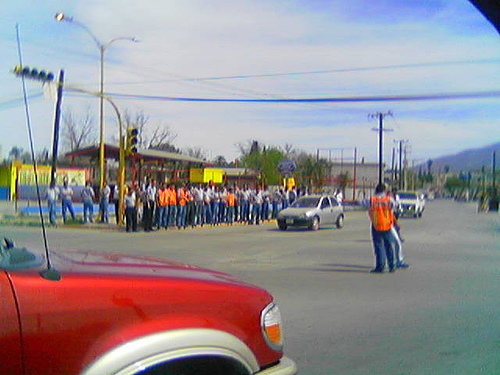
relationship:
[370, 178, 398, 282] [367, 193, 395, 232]
man wearing orange vest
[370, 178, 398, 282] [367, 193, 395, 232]
man wearing a vest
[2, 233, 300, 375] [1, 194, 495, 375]
suv driving on street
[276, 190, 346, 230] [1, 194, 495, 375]
car rolling on street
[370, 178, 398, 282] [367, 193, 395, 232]
man wearing vest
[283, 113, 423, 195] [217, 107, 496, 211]
powerlines are in distance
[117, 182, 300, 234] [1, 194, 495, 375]
people standing on street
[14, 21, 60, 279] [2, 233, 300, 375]
attenna in suv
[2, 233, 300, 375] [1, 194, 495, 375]
suv parked on street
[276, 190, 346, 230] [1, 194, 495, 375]
car driving on street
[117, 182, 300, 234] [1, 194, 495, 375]
people are beside street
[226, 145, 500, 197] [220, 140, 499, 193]
trees have leaves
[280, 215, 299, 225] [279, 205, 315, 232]
license plate in front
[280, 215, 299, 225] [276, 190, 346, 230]
license plate on car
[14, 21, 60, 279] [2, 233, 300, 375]
antenna in car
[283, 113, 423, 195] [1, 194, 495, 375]
powerlines are over street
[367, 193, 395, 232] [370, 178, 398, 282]
vest on a man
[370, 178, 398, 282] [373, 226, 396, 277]
man wearing jeans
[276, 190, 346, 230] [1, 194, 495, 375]
car on street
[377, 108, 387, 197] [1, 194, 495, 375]
pole along street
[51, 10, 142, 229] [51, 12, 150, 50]
pole have light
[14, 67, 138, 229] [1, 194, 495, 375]
traffic signal on street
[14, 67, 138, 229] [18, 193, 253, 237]
traffic signal on a side